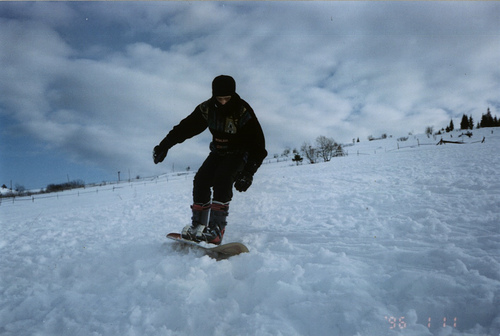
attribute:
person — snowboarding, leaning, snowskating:
[148, 70, 273, 246]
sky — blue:
[4, 4, 494, 182]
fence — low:
[3, 135, 499, 202]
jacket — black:
[162, 96, 275, 170]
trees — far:
[441, 109, 500, 133]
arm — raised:
[152, 102, 212, 165]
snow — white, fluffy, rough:
[2, 121, 497, 326]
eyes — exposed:
[215, 95, 232, 101]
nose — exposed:
[219, 98, 226, 105]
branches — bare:
[294, 133, 347, 153]